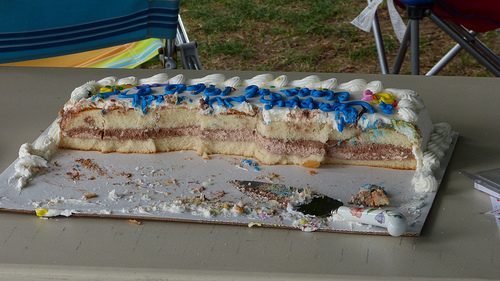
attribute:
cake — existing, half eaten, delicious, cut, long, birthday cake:
[7, 74, 454, 193]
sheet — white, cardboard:
[0, 114, 460, 237]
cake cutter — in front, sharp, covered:
[224, 178, 410, 239]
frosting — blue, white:
[62, 72, 424, 122]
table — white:
[0, 64, 500, 280]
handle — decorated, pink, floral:
[337, 204, 407, 237]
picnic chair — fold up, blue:
[1, 0, 205, 70]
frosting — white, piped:
[7, 115, 454, 195]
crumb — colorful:
[345, 182, 390, 207]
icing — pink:
[360, 88, 379, 102]